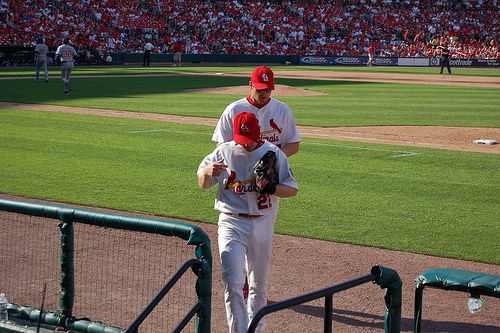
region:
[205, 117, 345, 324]
cardinals jersey number 22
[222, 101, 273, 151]
the player is looking at the ground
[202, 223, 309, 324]
the player has his leg lifted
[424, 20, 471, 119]
umpire in the field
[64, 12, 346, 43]
crowd sitting in the stand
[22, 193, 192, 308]
green railing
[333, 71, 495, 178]
the white base on the field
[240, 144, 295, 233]
glove on player's hand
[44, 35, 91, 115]
player in gray uniform is running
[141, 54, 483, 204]
field is grass and dirt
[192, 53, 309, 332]
two baseball players entering dugout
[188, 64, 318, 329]
two players wearing cardinals jerseys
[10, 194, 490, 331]
green railings of dugout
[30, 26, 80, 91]
two players in background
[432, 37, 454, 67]
umpire standing on field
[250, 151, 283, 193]
black glove of baseball player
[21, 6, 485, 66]
crowd watching the baseball game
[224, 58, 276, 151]
red caps of baseball players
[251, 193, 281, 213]
red 21 on white jersey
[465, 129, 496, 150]
white first base on field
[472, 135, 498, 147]
White base plate on dirt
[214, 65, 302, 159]
Man wearing red hat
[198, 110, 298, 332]
Man wearing red hat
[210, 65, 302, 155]
Man wearing Cardinals jersey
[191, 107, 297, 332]
Man wearing Cardinals jersey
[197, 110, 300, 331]
Man wearing black glove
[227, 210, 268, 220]
Red belt on pants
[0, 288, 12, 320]
Plastic water bottle next to fence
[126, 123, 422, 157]
White chalk line on grass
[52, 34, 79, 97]
Man wearing blue hat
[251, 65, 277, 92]
a red baseball cap with white letters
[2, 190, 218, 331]
a green covered fence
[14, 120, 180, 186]
a patch of shirt green grass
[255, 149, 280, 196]
a black and red baseball glove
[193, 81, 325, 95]
a sand pitches mound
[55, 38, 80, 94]
a guy running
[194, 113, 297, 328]
a baseball player in a white uniform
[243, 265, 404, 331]
a dark color stair railing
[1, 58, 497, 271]
a baseball feild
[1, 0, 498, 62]
a crowd of people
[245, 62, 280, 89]
Red cap of player in the back of first player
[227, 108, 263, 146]
First player wearing a red cap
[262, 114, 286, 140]
red Cardinal on front of second baseball player's top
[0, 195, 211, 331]
Green railing around baseball field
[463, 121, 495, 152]
White base plate sitting on the baseball field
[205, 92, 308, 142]
Red and white top of second baseball player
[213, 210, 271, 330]
White pants worn by first baseball player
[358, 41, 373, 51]
Man wearing a red shirt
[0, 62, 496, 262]
Grass on lthe baseball field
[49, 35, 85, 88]
Man walking away in the distance